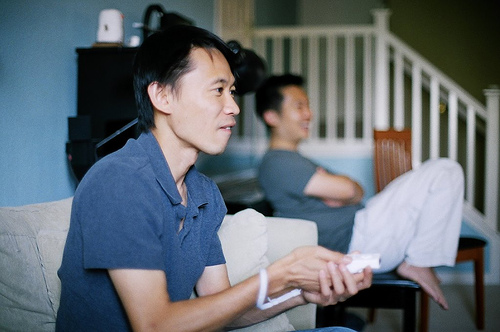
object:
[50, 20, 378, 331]
man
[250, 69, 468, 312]
man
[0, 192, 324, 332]
couch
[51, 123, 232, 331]
shirt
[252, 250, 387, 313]
controller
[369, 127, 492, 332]
chair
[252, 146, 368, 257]
shirt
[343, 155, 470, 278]
pants